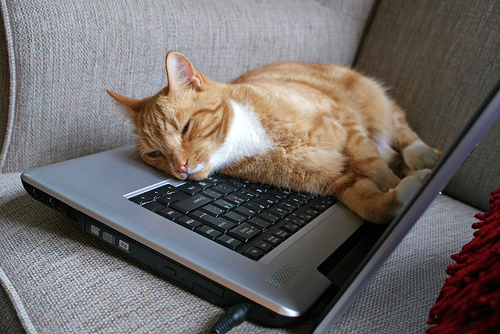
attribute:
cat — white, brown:
[105, 56, 435, 213]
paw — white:
[402, 141, 443, 172]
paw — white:
[392, 164, 434, 205]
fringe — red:
[427, 188, 498, 330]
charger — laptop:
[213, 304, 264, 331]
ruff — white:
[201, 82, 309, 182]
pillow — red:
[438, 206, 492, 313]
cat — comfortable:
[99, 42, 444, 240]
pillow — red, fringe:
[428, 205, 494, 309]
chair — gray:
[1, 3, 472, 333]